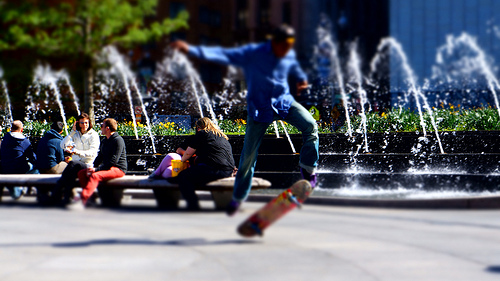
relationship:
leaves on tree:
[52, 18, 93, 55] [33, 14, 87, 45]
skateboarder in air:
[185, 36, 339, 203] [334, 58, 446, 176]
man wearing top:
[65, 118, 126, 211] [103, 128, 132, 167]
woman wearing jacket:
[56, 113, 113, 197] [56, 119, 119, 174]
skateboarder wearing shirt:
[170, 26, 320, 216] [222, 43, 306, 116]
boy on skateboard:
[169, 23, 321, 215] [240, 184, 313, 240]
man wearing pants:
[80, 121, 132, 199] [84, 167, 125, 202]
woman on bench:
[158, 116, 233, 211] [108, 173, 271, 213]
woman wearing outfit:
[166, 117, 234, 211] [160, 130, 233, 193]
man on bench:
[65, 118, 126, 211] [1, 169, 275, 210]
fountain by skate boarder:
[28, 62, 65, 136] [175, 25, 324, 242]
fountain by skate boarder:
[89, 45, 158, 160] [175, 25, 324, 242]